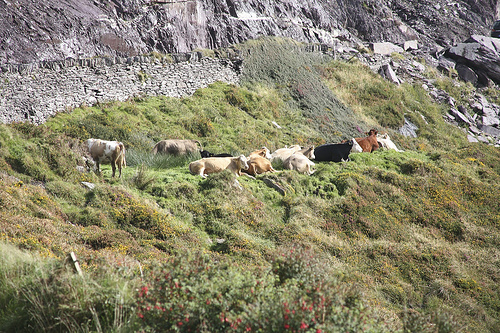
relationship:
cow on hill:
[347, 132, 378, 152] [257, 150, 478, 320]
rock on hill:
[367, 39, 406, 57] [176, 42, 484, 176]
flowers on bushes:
[378, 190, 454, 222] [286, 159, 481, 320]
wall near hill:
[14, 48, 238, 118] [6, 104, 266, 330]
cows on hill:
[76, 133, 398, 181] [29, 98, 477, 330]